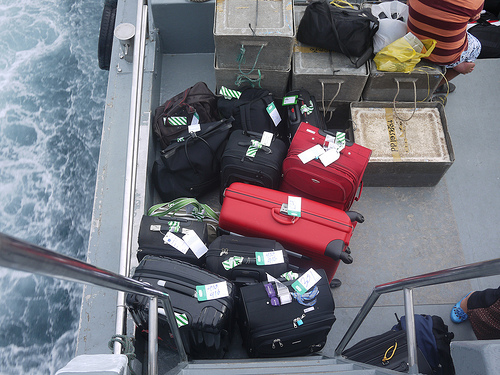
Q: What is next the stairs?
A: A piece of black luggage.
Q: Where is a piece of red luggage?
A: Next to other luggage.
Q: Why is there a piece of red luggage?
A: It is among other luggage on transit.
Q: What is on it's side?
A: A red suitcase.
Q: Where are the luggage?
A: At the bottom of the stairs.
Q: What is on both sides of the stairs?
A: Silver railings.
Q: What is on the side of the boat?
A: Choppy water.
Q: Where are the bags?
A: In a boat.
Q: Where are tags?
A: On the bags.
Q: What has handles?
A: The bags.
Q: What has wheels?
A: Red bag.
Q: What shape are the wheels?
A: Round.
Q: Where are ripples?
A: In the water.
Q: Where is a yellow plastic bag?
A: On a box.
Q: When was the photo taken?
A: Daytime.